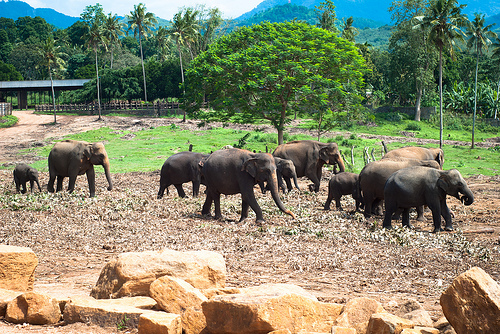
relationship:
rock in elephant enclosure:
[0, 243, 500, 334] [2, 103, 497, 332]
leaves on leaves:
[179, 21, 366, 127] [179, 21, 370, 144]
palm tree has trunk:
[393, 2, 469, 148] [439, 61, 443, 148]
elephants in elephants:
[9, 138, 475, 230] [0, 51, 500, 333]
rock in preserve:
[0, 243, 497, 332] [3, 102, 497, 332]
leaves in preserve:
[179, 21, 370, 144] [3, 102, 497, 332]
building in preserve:
[0, 79, 93, 112] [3, 102, 497, 332]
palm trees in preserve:
[71, 2, 158, 122] [3, 102, 497, 332]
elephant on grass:
[196, 144, 297, 224] [0, 175, 497, 295]